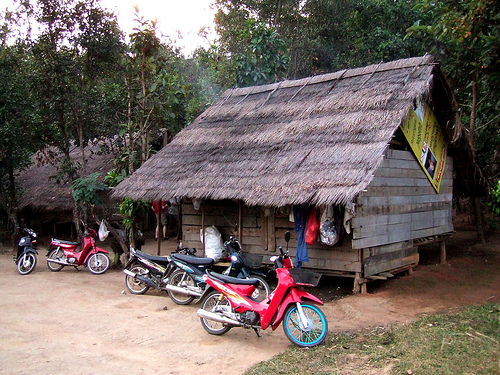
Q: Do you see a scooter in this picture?
A: Yes, there is a scooter.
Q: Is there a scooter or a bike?
A: Yes, there is a scooter.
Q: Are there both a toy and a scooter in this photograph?
A: No, there is a scooter but no toys.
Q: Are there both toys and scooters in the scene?
A: No, there is a scooter but no toys.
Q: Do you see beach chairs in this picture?
A: No, there are no beach chairs.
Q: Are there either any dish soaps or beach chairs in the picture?
A: No, there are no beach chairs or dish soaps.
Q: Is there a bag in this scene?
A: Yes, there is a bag.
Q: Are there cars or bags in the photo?
A: Yes, there is a bag.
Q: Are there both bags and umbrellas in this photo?
A: No, there is a bag but no umbrellas.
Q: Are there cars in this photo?
A: No, there are no cars.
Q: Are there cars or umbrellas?
A: No, there are no cars or umbrellas.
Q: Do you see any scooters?
A: Yes, there is a scooter.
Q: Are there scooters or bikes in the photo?
A: Yes, there is a scooter.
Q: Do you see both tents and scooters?
A: No, there is a scooter but no tents.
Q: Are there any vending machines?
A: No, there are no vending machines.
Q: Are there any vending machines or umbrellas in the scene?
A: No, there are no vending machines or umbrellas.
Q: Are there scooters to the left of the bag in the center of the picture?
A: Yes, there is a scooter to the left of the bag.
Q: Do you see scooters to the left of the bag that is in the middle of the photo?
A: Yes, there is a scooter to the left of the bag.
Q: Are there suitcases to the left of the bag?
A: No, there is a scooter to the left of the bag.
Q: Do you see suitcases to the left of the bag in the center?
A: No, there is a scooter to the left of the bag.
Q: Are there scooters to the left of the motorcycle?
A: Yes, there is a scooter to the left of the motorcycle.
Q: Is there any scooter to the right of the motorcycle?
A: No, the scooter is to the left of the motorcycle.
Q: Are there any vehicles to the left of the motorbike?
A: No, there is a scooter to the left of the motorbike.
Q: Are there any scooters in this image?
A: Yes, there is a scooter.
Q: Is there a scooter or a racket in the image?
A: Yes, there is a scooter.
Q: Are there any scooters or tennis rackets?
A: Yes, there is a scooter.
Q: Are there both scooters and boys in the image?
A: No, there is a scooter but no boys.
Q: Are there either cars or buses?
A: No, there are no cars or buses.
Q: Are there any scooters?
A: Yes, there is a scooter.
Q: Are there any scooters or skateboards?
A: Yes, there is a scooter.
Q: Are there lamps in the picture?
A: No, there are no lamps.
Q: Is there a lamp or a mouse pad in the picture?
A: No, there are no lamps or mouse pads.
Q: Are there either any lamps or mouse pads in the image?
A: No, there are no lamps or mouse pads.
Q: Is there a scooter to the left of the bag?
A: Yes, there is a scooter to the left of the bag.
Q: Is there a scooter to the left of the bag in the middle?
A: Yes, there is a scooter to the left of the bag.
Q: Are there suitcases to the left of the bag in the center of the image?
A: No, there is a scooter to the left of the bag.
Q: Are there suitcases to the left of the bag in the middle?
A: No, there is a scooter to the left of the bag.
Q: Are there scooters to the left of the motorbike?
A: Yes, there is a scooter to the left of the motorbike.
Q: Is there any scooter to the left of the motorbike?
A: Yes, there is a scooter to the left of the motorbike.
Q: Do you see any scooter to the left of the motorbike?
A: Yes, there is a scooter to the left of the motorbike.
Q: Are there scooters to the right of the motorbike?
A: No, the scooter is to the left of the motorbike.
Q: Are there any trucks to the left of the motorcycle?
A: No, there is a scooter to the left of the motorcycle.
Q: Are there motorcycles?
A: Yes, there is a motorcycle.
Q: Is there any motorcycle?
A: Yes, there is a motorcycle.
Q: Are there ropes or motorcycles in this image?
A: Yes, there is a motorcycle.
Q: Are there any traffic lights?
A: No, there are no traffic lights.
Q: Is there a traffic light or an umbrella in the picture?
A: No, there are no traffic lights or umbrellas.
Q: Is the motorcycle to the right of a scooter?
A: Yes, the motorcycle is to the right of a scooter.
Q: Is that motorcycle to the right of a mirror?
A: No, the motorcycle is to the right of a scooter.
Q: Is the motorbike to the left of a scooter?
A: No, the motorbike is to the right of a scooter.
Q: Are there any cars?
A: No, there are no cars.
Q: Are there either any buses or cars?
A: No, there are no cars or buses.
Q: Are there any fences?
A: No, there are no fences.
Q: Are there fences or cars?
A: No, there are no fences or cars.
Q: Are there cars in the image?
A: No, there are no cars.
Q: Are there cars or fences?
A: No, there are no cars or fences.